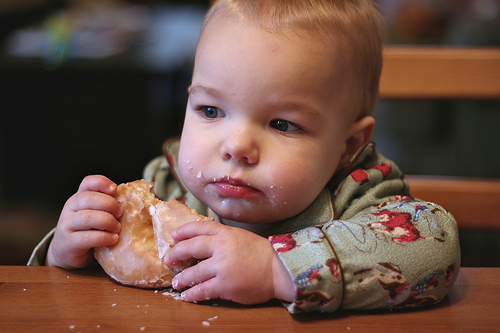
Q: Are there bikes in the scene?
A: No, there are no bikes.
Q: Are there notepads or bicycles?
A: No, there are no bicycles or notepads.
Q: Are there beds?
A: No, there are no beds.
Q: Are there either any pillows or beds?
A: No, there are no beds or pillows.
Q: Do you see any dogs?
A: No, there are no dogs.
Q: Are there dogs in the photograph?
A: No, there are no dogs.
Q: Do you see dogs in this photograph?
A: No, there are no dogs.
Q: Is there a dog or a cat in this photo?
A: No, there are no dogs or cats.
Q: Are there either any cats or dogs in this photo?
A: No, there are no dogs or cats.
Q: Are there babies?
A: Yes, there is a baby.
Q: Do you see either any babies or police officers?
A: Yes, there is a baby.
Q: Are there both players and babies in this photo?
A: No, there is a baby but no players.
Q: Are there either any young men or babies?
A: Yes, there is a young baby.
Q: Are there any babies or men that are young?
A: Yes, the baby is young.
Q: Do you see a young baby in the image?
A: Yes, there is a young baby.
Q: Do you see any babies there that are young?
A: Yes, there is a baby that is young.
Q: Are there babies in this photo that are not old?
A: Yes, there is an young baby.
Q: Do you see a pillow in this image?
A: No, there are no pillows.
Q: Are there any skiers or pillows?
A: No, there are no pillows or skiers.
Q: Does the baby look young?
A: Yes, the baby is young.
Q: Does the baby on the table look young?
A: Yes, the baby is young.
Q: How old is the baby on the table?
A: The baby is young.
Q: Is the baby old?
A: No, the baby is young.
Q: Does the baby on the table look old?
A: No, the baby is young.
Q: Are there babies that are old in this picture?
A: No, there is a baby but he is young.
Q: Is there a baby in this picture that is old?
A: No, there is a baby but he is young.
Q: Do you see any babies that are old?
A: No, there is a baby but he is young.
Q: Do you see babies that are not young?
A: No, there is a baby but he is young.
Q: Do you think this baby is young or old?
A: The baby is young.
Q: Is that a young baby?
A: Yes, that is a young baby.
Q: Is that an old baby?
A: No, that is a young baby.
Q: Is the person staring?
A: Yes, the baby is staring.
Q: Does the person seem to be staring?
A: Yes, the baby is staring.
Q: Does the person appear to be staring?
A: Yes, the baby is staring.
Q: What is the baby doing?
A: The baby is staring.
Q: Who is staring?
A: The baby is staring.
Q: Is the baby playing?
A: No, the baby is staring.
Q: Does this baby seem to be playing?
A: No, the baby is staring.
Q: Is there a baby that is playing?
A: No, there is a baby but he is staring.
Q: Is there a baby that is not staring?
A: No, there is a baby but he is staring.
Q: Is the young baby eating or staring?
A: The baby is staring.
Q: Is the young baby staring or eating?
A: The baby is staring.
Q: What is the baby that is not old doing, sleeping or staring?
A: The baby is staring.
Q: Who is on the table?
A: The baby is on the table.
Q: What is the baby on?
A: The baby is on the table.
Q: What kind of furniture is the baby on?
A: The baby is on the table.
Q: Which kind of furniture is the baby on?
A: The baby is on the table.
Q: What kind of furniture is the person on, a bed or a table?
A: The baby is on a table.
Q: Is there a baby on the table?
A: Yes, there is a baby on the table.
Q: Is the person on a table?
A: Yes, the baby is on a table.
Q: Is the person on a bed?
A: No, the baby is on a table.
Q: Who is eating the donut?
A: The baby is eating the donut.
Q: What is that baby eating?
A: The baby is eating a donut.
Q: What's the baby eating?
A: The baby is eating a donut.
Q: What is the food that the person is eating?
A: The food is a donut.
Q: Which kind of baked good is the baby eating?
A: The baby is eating a donut.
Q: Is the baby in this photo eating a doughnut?
A: Yes, the baby is eating a doughnut.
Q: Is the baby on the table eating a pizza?
A: No, the baby is eating a doughnut.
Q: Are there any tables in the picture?
A: Yes, there is a table.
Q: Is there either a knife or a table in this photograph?
A: Yes, there is a table.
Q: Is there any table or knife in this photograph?
A: Yes, there is a table.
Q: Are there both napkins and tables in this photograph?
A: No, there is a table but no napkins.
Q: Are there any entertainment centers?
A: No, there are no entertainment centers.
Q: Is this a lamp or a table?
A: This is a table.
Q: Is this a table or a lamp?
A: This is a table.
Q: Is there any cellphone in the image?
A: No, there are no cell phones.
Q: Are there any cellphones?
A: No, there are no cellphones.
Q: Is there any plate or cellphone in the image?
A: No, there are no cell phones or plates.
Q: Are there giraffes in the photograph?
A: No, there are no giraffes.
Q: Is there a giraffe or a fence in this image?
A: No, there are no giraffes or fences.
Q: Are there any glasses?
A: No, there are no glasses.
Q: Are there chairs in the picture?
A: Yes, there is a chair.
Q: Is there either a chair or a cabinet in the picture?
A: Yes, there is a chair.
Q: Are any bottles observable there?
A: No, there are no bottles.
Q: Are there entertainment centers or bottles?
A: No, there are no bottles or entertainment centers.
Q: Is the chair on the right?
A: Yes, the chair is on the right of the image.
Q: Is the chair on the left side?
A: No, the chair is on the right of the image.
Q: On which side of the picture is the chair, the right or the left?
A: The chair is on the right of the image.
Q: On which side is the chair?
A: The chair is on the right of the image.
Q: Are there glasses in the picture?
A: No, there are no glasses.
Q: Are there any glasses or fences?
A: No, there are no glasses or fences.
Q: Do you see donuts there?
A: Yes, there is a donut.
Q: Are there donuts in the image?
A: Yes, there is a donut.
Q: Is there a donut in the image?
A: Yes, there is a donut.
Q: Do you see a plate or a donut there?
A: Yes, there is a donut.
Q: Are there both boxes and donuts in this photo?
A: No, there is a donut but no boxes.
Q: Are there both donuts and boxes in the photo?
A: No, there is a donut but no boxes.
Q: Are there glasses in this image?
A: No, there are no glasses.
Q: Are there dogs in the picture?
A: No, there are no dogs.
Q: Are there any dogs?
A: No, there are no dogs.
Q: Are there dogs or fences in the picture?
A: No, there are no dogs or fences.